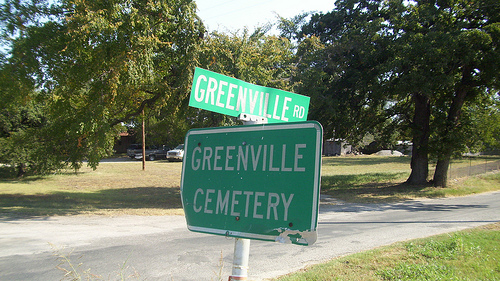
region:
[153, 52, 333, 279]
traffic signs on a steel pole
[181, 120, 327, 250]
green traffic sign on poll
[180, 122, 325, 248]
street sign on a green plate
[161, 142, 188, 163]
car parked on street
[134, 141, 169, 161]
car parked on street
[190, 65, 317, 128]
street name sign on steel poll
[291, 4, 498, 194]
a tall tree with stem and branches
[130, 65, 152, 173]
a wooden stick poll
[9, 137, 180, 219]
a plain grassy field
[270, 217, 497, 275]
a grassy field on sidewalk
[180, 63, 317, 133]
small sign on top of pole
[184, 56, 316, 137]
small sign reads greenville rd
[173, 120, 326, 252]
large sign on post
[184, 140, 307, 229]
words on sign read greenville cemetery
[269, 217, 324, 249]
corner of sign is ripped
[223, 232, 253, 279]
post holds two signs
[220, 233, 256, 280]
post holding signs is white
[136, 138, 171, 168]
truck parked behind grass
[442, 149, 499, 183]
fence dividing grass and road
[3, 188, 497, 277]
empty road running between grass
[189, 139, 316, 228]
green lettering on the sign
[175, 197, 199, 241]
sign is bent in corner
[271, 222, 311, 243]
paint is chipped on sign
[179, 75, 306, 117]
street sign on a pole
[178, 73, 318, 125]
sign is bent in the middle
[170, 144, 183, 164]
a white car is parked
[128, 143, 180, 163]
two cars are parked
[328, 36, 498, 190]
two large trees by the road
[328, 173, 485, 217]
shadow from the sunlight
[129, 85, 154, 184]
pole in middle of lawn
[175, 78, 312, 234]
these are the posts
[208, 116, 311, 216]
the post is green in color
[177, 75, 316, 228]
the post is short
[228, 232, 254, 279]
this is the post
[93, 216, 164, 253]
this is the road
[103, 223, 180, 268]
the road is tarmacked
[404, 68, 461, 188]
these are the trees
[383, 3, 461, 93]
the trees are leafy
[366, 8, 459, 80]
the leaves re green in color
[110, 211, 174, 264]
the road is clean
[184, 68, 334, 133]
a green board in road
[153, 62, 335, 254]
two green boards in road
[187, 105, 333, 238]
white text written in board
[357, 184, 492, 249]
shadow of the trees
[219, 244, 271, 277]
a white stand on road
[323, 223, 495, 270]
a view of the grass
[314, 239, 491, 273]
green grass on the road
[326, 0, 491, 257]
a big tree in road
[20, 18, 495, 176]
a group of trees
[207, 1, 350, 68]
a cool view of sky